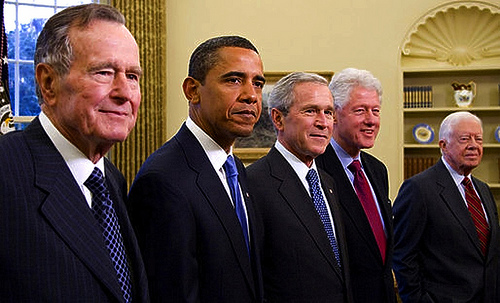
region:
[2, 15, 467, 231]
Five American presidents stand in a row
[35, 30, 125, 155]
George H.W.Bush is George W. Bush's father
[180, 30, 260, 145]
Barack Obama who was elected in 2008 from Illinois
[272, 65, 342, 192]
George W. Bush from Texas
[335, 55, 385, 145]
Bill Clinton from Arkansas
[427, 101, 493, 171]
Jimmy Carter from the state of Georgia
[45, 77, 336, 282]
George H.W. Bush, Barack Obama and George W. Bush wear blue ties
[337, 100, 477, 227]
Bill Clinton and Jimmy Carter wear red ties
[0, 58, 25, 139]
Flag in the corner of the room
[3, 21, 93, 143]
Window behind George H. W. Bush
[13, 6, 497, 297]
Four men who were presidents of the USA.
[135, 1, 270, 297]
Barack Obama the 44th president of the USA.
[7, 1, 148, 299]
George H. Bush the 41st president of the USA.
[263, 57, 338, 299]
George W. Bush the 43rd president of the USA.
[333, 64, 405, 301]
Bill Clinton the 42nd president of the USA.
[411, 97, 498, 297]
Jimmy Carter the 39th president of the USA.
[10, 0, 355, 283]
Three men have on blue ties.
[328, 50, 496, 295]
Two men have on red ties.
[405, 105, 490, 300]
Jimmy Carter has solid white hair.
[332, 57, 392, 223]
Bill Clinton has white hair.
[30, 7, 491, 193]
five US Presidents standing in a row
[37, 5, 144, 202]
President George H. W. Bush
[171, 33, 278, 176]
President Barack Obama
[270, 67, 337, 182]
President George W. Bush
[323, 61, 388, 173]
President William Jefferson Clinton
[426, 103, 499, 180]
President Jimmy Carter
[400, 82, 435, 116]
blue and gold books on a shelf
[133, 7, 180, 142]
gold drapes on the window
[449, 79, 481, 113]
brown and white pitcher on shelf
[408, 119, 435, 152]
blue and white decorative plate on shelf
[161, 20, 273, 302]
president obama wearing a blue tie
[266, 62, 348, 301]
bush wearing a blue tie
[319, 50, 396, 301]
Clinton wearing a red tie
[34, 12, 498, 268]
five men wearing suits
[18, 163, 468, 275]
black suits and ties on the men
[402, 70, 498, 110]
shelf with books and vase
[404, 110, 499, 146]
plates on a shelf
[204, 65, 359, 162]
painting behind the men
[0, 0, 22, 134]
flag behind the men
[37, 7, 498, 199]
men posing for a photo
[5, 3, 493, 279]
Presidents of the United States past and present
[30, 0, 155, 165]
This is George Bush Senior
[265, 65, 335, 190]
This is George W Bush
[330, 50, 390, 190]
This is Bill Clinton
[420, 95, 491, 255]
This is Jimmy Carter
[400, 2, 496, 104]
A shelf is set into the wall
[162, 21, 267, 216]
This is Barack Obama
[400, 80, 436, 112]
Books are on the shelf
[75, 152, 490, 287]
They are all wearing ties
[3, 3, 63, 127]
A window is behind them